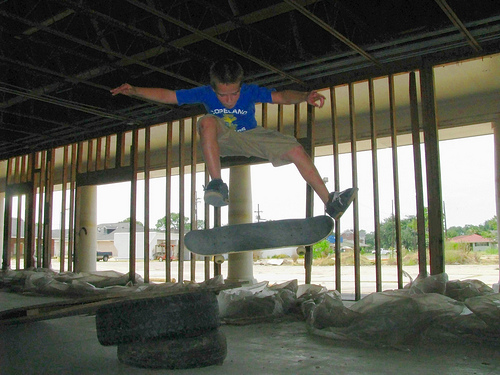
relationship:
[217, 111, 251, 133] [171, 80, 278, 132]
designs screen printed onto t-shirt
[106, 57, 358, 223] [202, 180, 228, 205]
boy wearing shoe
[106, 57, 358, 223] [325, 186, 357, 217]
boy wearing shoe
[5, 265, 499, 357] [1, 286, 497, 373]
sheeting lying on floor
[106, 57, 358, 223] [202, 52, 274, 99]
boy has hair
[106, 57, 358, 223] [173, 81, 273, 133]
boy wearing t-shirt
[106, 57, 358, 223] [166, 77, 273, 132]
boy wearing t-shirt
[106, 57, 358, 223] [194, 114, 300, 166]
boy wearing shorts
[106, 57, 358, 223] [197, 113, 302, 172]
boy wearing shorts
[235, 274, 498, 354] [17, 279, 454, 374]
plastic on floor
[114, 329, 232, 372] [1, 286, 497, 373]
tires on floor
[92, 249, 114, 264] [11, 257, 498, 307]
pickup truck on parking lot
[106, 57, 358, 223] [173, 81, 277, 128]
boy wearing t-shirt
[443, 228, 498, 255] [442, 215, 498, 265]
building has roof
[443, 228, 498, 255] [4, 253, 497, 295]
building passing parking lot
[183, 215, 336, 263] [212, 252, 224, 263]
skateboard has wheel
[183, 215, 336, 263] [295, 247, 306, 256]
skateboard has wheel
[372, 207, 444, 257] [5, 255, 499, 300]
trees passing parking lot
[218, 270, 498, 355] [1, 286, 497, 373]
plastic on floor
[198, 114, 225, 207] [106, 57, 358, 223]
leg of boy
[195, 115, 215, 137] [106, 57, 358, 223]
knee of boy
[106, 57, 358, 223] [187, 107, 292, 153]
boy wearing shorts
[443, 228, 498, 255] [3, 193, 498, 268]
building in background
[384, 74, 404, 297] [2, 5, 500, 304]
wall under building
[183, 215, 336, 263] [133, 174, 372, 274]
skateboard in mid air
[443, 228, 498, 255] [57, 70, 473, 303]
building in background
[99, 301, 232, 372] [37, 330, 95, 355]
tires are on floor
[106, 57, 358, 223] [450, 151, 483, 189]
boy jumping in air